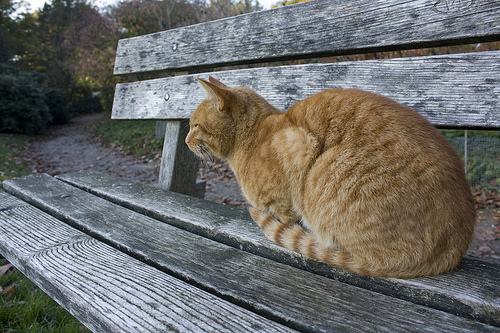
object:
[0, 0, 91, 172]
distance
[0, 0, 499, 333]
park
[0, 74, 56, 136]
bushes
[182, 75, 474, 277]
cat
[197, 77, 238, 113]
ear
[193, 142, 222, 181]
whisker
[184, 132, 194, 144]
nose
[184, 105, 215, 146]
face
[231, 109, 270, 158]
neck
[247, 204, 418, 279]
tail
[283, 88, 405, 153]
back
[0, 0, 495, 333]
bench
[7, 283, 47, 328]
grass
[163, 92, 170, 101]
bolt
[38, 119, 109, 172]
path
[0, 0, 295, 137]
tree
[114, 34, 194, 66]
slat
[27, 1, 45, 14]
sky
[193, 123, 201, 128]
eye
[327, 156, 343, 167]
fur